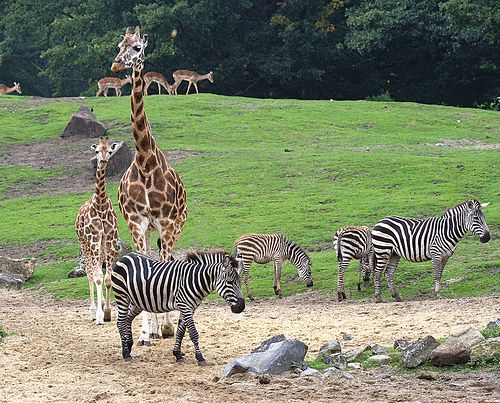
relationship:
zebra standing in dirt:
[109, 247, 247, 371] [5, 300, 484, 393]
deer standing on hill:
[172, 70, 214, 96] [5, 87, 481, 230]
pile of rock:
[248, 329, 483, 375] [223, 337, 307, 377]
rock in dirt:
[223, 337, 307, 377] [5, 300, 484, 393]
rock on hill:
[61, 104, 112, 141] [0, 92, 498, 303]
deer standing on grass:
[96, 75, 133, 97] [0, 90, 497, 400]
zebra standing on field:
[373, 207, 485, 300] [27, 63, 460, 301]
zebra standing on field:
[109, 247, 247, 371] [0, 91, 498, 297]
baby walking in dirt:
[73, 135, 119, 325] [3, 285, 495, 400]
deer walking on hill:
[162, 61, 217, 97] [97, 89, 454, 221]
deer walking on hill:
[172, 70, 214, 96] [12, 83, 489, 249]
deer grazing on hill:
[143, 67, 173, 98] [6, 83, 475, 295]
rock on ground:
[223, 333, 308, 377] [0, 93, 497, 401]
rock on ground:
[428, 336, 470, 366] [0, 93, 497, 401]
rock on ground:
[468, 335, 499, 366] [0, 93, 497, 401]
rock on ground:
[400, 335, 440, 367] [0, 93, 497, 401]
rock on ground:
[367, 355, 393, 366] [0, 93, 497, 401]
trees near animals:
[1, 0, 500, 98] [71, 207, 489, 372]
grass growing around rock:
[303, 329, 499, 370] [224, 334, 306, 381]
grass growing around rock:
[303, 329, 499, 370] [318, 338, 335, 369]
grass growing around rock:
[303, 329, 499, 370] [471, 336, 497, 365]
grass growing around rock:
[303, 329, 499, 370] [425, 326, 485, 364]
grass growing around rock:
[303, 329, 499, 370] [399, 338, 437, 370]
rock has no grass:
[85, 137, 138, 186] [2, 95, 498, 300]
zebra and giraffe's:
[109, 247, 247, 371] [71, 20, 193, 353]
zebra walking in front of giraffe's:
[109, 247, 247, 371] [71, 20, 193, 353]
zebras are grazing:
[95, 212, 495, 354] [236, 218, 374, 298]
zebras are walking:
[95, 212, 495, 354] [111, 248, 245, 366]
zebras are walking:
[95, 212, 495, 354] [370, 201, 485, 298]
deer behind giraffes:
[95, 67, 214, 95] [75, 20, 185, 318]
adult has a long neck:
[109, 23, 186, 346] [126, 68, 157, 156]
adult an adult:
[109, 23, 186, 346] [109, 21, 186, 259]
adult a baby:
[109, 23, 186, 346] [73, 133, 121, 326]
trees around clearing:
[3, 0, 480, 101] [4, 95, 484, 391]